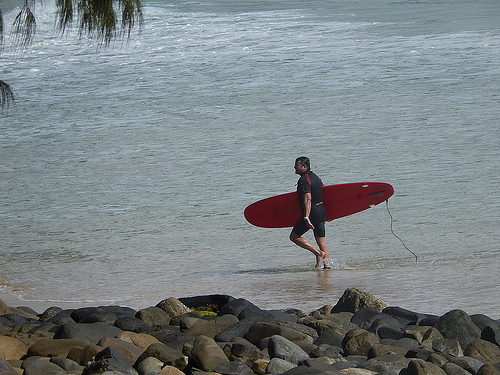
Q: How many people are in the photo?
A: One.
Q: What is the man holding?
A: A surfboard.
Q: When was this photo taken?
A: In the daytime.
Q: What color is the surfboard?
A: Red.